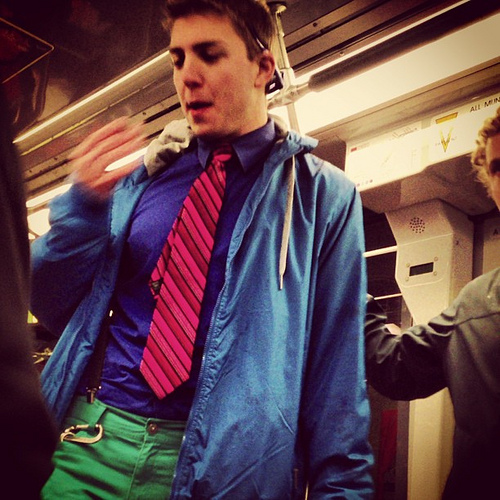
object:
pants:
[37, 397, 181, 500]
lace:
[278, 156, 296, 291]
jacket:
[26, 126, 374, 499]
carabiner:
[58, 424, 103, 445]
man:
[364, 109, 497, 498]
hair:
[468, 107, 499, 203]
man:
[38, 0, 378, 497]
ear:
[254, 49, 275, 88]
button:
[147, 422, 158, 435]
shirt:
[88, 118, 277, 421]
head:
[161, 7, 276, 138]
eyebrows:
[168, 39, 224, 56]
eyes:
[171, 47, 225, 69]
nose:
[181, 54, 203, 87]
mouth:
[185, 99, 216, 117]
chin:
[193, 122, 230, 139]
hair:
[160, 0, 275, 60]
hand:
[68, 114, 148, 205]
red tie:
[138, 148, 232, 400]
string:
[279, 146, 296, 290]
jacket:
[365, 266, 499, 500]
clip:
[60, 424, 104, 445]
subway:
[2, 1, 500, 499]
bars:
[5, 4, 492, 496]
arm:
[27, 157, 121, 339]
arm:
[364, 294, 454, 403]